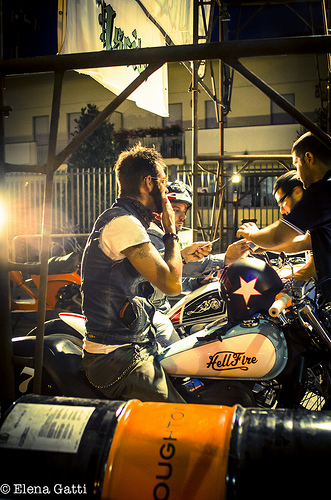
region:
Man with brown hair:
[101, 134, 185, 224]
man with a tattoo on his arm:
[125, 237, 163, 276]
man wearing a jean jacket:
[79, 204, 163, 343]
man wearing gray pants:
[74, 341, 186, 417]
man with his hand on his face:
[149, 185, 184, 227]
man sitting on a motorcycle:
[45, 267, 195, 422]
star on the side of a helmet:
[233, 257, 265, 303]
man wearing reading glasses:
[267, 184, 290, 212]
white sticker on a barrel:
[4, 402, 100, 460]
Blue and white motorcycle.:
[158, 278, 328, 407]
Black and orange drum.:
[0, 395, 330, 499]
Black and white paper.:
[0, 400, 95, 451]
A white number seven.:
[17, 366, 34, 393]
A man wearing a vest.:
[77, 141, 181, 402]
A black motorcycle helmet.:
[196, 257, 284, 342]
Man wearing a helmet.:
[166, 179, 194, 230]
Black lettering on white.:
[204, 348, 257, 371]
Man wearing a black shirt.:
[236, 131, 329, 295]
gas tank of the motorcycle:
[160, 314, 290, 377]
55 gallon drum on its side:
[2, 391, 329, 499]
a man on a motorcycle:
[78, 148, 182, 404]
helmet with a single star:
[218, 258, 281, 327]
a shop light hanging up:
[230, 169, 240, 183]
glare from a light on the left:
[0, 190, 73, 264]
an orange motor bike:
[5, 251, 83, 314]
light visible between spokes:
[299, 393, 327, 412]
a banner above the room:
[55, 0, 169, 117]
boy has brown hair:
[116, 139, 164, 208]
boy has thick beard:
[142, 165, 168, 217]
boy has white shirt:
[86, 217, 138, 348]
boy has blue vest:
[100, 203, 145, 331]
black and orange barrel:
[28, 383, 321, 491]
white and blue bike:
[150, 302, 265, 385]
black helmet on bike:
[212, 258, 260, 325]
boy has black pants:
[81, 342, 178, 390]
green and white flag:
[56, 12, 186, 90]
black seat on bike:
[18, 325, 80, 377]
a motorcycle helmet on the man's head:
[164, 178, 199, 202]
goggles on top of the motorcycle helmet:
[166, 178, 194, 196]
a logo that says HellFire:
[205, 348, 259, 371]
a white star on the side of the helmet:
[231, 273, 262, 305]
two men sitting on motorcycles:
[76, 125, 220, 407]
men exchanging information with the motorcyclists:
[234, 131, 329, 299]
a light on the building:
[229, 169, 241, 183]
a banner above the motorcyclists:
[55, 0, 175, 118]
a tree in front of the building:
[60, 98, 119, 229]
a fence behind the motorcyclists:
[3, 159, 297, 267]